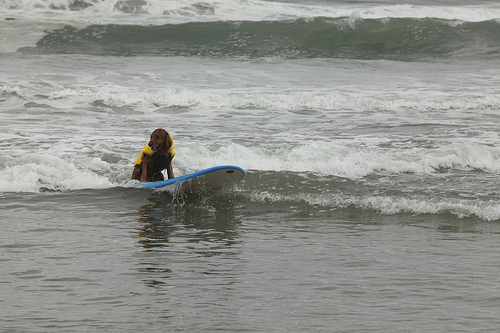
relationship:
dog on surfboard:
[131, 128, 174, 182] [114, 162, 246, 201]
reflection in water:
[132, 188, 246, 287] [3, 0, 498, 330]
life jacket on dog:
[134, 134, 176, 167] [131, 128, 174, 182]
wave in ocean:
[1, 27, 498, 163] [0, 0, 499, 331]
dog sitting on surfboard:
[131, 128, 174, 182] [114, 162, 246, 201]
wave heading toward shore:
[1, 27, 498, 163] [0, 173, 499, 331]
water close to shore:
[3, 0, 498, 330] [0, 173, 499, 331]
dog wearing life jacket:
[131, 128, 174, 182] [133, 130, 176, 168]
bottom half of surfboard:
[132, 166, 244, 200] [117, 164, 248, 194]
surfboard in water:
[117, 164, 248, 194] [3, 0, 498, 330]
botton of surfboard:
[124, 168, 243, 204] [121, 163, 246, 197]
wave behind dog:
[1, 0, 499, 163] [131, 128, 174, 182]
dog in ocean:
[131, 128, 174, 182] [0, 0, 499, 331]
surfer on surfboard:
[130, 128, 175, 179] [142, 165, 245, 193]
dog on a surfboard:
[131, 128, 174, 182] [132, 162, 247, 193]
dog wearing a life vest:
[131, 128, 174, 182] [134, 140, 176, 162]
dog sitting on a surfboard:
[133, 124, 178, 183] [141, 163, 247, 195]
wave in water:
[1, 27, 498, 163] [26, 1, 386, 129]